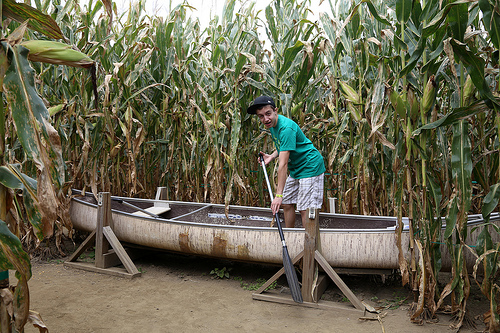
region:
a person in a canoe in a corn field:
[62, 81, 497, 317]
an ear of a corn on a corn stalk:
[16, 35, 92, 71]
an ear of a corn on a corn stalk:
[418, 78, 433, 111]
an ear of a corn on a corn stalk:
[457, 72, 474, 105]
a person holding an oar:
[236, 88, 331, 313]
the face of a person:
[256, 107, 276, 129]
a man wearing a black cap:
[242, 88, 333, 227]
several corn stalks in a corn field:
[108, 0, 245, 205]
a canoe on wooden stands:
[56, 185, 496, 319]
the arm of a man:
[268, 137, 291, 217]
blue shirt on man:
[252, 112, 330, 177]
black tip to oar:
[261, 246, 306, 301]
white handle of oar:
[241, 162, 281, 219]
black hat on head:
[250, 91, 275, 112]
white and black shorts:
[271, 169, 338, 214]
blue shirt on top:
[258, 113, 326, 175]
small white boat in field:
[55, 201, 405, 263]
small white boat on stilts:
[61, 188, 426, 266]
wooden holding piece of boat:
[257, 215, 367, 316]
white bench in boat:
[135, 203, 166, 224]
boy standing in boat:
[248, 76, 345, 303]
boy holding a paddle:
[247, 105, 309, 332]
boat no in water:
[120, 200, 289, 307]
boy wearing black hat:
[243, 84, 341, 171]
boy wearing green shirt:
[259, 99, 353, 188]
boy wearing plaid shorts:
[265, 135, 337, 227]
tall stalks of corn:
[325, 36, 423, 190]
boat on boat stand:
[67, 183, 367, 311]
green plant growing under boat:
[183, 253, 265, 292]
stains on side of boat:
[172, 225, 252, 256]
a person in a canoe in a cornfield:
[5, 6, 495, 328]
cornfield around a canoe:
[9, 2, 486, 295]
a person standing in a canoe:
[247, 82, 356, 280]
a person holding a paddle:
[245, 91, 317, 299]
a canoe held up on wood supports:
[62, 185, 497, 307]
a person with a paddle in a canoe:
[64, 73, 498, 273]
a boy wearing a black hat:
[248, 91, 274, 113]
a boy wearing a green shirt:
[266, 121, 328, 176]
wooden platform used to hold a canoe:
[61, 191, 141, 276]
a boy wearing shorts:
[277, 167, 327, 213]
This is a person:
[240, 78, 348, 300]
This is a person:
[235, 72, 345, 277]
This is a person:
[246, 80, 348, 299]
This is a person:
[243, 80, 338, 290]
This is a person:
[235, 87, 342, 312]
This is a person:
[239, 82, 324, 319]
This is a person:
[245, 85, 334, 325]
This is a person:
[246, 87, 326, 328]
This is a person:
[243, 82, 328, 302]